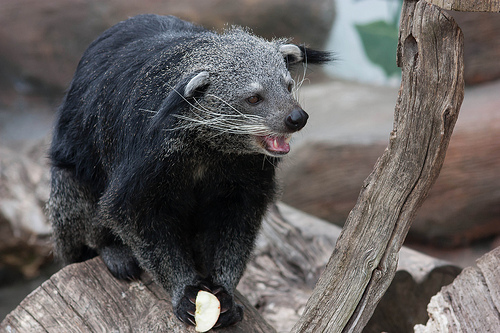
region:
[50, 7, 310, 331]
animal has mouth open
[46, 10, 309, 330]
animal holds food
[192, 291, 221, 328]
food is held by animal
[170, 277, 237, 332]
paws hold food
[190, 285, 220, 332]
food is held by paws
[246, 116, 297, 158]
mouth is open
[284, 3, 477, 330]
wood is to right of animal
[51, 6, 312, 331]
animal sits on wood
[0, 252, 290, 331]
wood is underneath animal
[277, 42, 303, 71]
ear is on head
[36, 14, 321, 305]
a black and gray animal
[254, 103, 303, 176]
open mouth of animal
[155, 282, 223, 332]
white piece of food in paws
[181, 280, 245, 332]
claws on the paws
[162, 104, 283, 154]
white whiskers on animal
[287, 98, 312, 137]
black nose of animal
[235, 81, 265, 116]
a brown eye on animal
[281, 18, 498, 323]
a stick by the animal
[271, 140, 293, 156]
pink tongue of the animal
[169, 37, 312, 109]
little gray ears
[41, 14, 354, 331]
this is a binturong. yes i'm the only one of, say, two. who'll know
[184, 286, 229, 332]
piece of apple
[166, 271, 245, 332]
two clawed paws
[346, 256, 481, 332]
binturong shadow, maybe w/ wood added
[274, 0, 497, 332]
a slightly curved branch in an animal park, likely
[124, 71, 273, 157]
extremely long white cheek whiskers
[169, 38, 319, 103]
rounded grey ears, held slightly forward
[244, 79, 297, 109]
brown eyes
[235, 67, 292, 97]
white, cloudlike eyebrow thingies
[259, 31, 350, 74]
the fluffy brushy end of a tail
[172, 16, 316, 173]
the animal has sand on its head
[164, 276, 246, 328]
the animal is holding an egg shell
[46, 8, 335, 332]
the animal has black fur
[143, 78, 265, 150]
the animal has long whiskers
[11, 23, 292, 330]
the animal sits on a log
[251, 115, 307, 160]
the animal has it's mouth open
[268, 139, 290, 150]
a few of the animals teeth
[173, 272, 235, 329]
the animal has claws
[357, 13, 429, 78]
a leaf is in the background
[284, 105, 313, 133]
the animals nose is black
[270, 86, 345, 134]
the nose of a animal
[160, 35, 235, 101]
the ear of a animal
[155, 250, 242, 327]
the paw of a animal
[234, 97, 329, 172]
the mouth of a animal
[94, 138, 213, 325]
the arms of a animal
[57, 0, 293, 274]
the body of a animal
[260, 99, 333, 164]
the teeth of a animal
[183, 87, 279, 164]
the whiskers of a animal